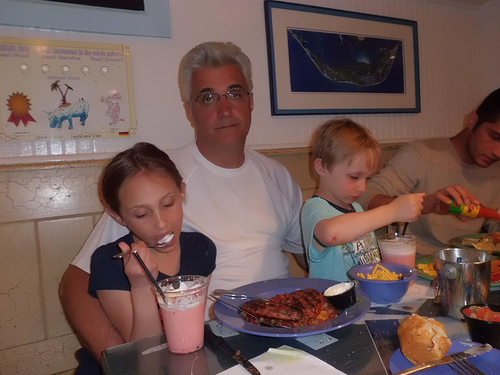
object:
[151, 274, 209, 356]
milkshake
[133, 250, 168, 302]
straw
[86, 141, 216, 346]
people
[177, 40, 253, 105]
hair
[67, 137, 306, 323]
shirt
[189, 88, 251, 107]
glasses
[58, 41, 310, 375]
man